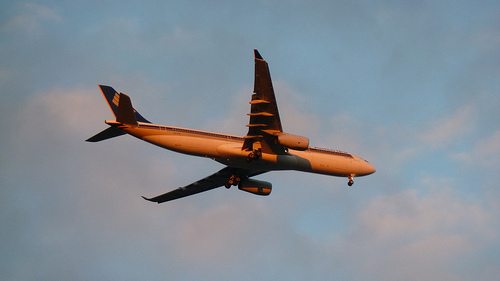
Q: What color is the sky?
A: Blue.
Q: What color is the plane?
A: White.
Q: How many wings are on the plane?
A: Two.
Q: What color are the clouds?
A: White.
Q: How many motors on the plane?
A: Two.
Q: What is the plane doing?
A: Flying.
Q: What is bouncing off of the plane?
A: Sunlight.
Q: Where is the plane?
A: In the air.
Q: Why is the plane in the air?
A: Flying.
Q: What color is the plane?
A: Orange.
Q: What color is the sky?
A: Blue.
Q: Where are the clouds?
A: In the sky.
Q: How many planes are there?
A: 1.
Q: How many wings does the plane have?
A: 2.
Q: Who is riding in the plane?
A: Passengers.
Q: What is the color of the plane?
A: Orange.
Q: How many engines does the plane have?
A: Two.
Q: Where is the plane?
A: The sky.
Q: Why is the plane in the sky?
A: It is flying.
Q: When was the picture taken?
A: During the day.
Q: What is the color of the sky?
A: Blue.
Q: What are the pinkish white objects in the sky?
A: Clouds.